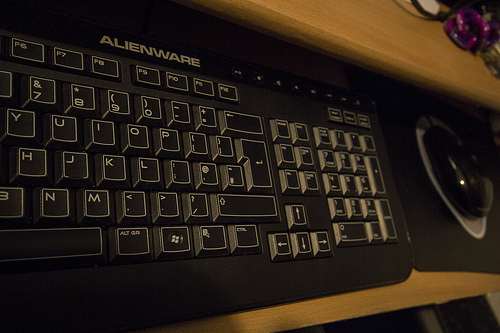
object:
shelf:
[194, 0, 499, 109]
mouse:
[420, 120, 494, 220]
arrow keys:
[287, 230, 314, 260]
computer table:
[133, 0, 499, 332]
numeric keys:
[326, 196, 351, 222]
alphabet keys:
[39, 186, 73, 217]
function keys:
[216, 81, 239, 104]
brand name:
[96, 35, 203, 67]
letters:
[42, 192, 56, 202]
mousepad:
[370, 102, 499, 273]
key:
[155, 223, 191, 259]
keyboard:
[0, 1, 413, 332]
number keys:
[329, 220, 372, 247]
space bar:
[0, 226, 105, 262]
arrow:
[317, 239, 329, 245]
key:
[308, 230, 335, 258]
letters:
[97, 34, 113, 48]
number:
[142, 107, 154, 118]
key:
[136, 95, 164, 122]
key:
[264, 231, 293, 261]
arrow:
[276, 242, 287, 248]